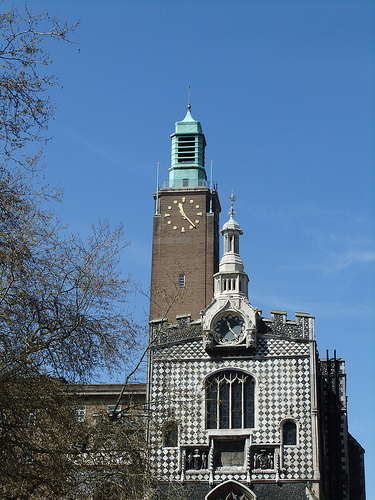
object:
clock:
[164, 197, 202, 232]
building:
[149, 82, 221, 322]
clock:
[212, 310, 247, 345]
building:
[147, 191, 366, 499]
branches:
[1, 0, 188, 500]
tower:
[168, 85, 208, 186]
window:
[205, 368, 256, 430]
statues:
[187, 448, 207, 470]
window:
[179, 274, 187, 288]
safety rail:
[159, 179, 211, 190]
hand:
[230, 329, 239, 339]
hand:
[227, 321, 232, 330]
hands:
[178, 202, 196, 227]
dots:
[168, 205, 172, 210]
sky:
[3, 3, 375, 399]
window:
[282, 418, 300, 447]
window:
[162, 420, 178, 449]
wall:
[148, 338, 314, 480]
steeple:
[213, 190, 250, 299]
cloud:
[258, 295, 372, 322]